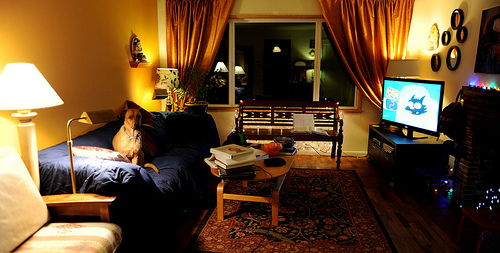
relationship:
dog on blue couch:
[112, 101, 158, 179] [37, 110, 222, 248]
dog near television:
[112, 101, 158, 179] [378, 77, 443, 138]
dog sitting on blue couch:
[112, 101, 158, 179] [37, 110, 222, 248]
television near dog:
[378, 77, 443, 138] [112, 101, 158, 179]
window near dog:
[238, 24, 323, 96] [112, 101, 158, 179]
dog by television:
[112, 101, 158, 179] [378, 77, 443, 138]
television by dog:
[378, 77, 443, 138] [112, 101, 158, 179]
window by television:
[238, 24, 323, 96] [378, 77, 443, 138]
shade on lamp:
[0, 60, 60, 110] [4, 65, 54, 193]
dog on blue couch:
[112, 108, 161, 173] [37, 107, 218, 248]